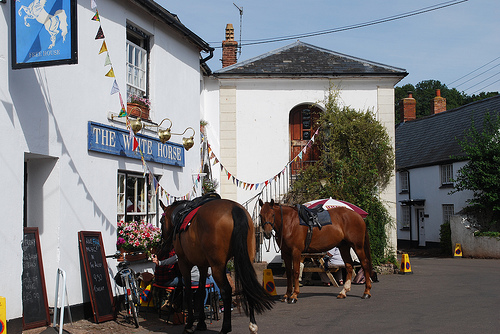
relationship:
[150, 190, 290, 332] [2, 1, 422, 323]
horse near building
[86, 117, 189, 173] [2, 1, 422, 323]
plaque on building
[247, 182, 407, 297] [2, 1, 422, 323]
horse face building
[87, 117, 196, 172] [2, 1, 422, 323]
blue sign on building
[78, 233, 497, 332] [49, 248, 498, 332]
asphalt on ground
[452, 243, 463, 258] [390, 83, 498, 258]
cone next building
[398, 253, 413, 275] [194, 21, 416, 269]
cone next building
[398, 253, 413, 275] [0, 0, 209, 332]
cone next building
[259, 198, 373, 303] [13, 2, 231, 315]
horse next building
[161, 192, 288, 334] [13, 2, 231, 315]
horse next building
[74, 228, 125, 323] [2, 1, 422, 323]
chalk board against building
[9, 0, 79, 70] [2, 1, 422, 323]
sign on building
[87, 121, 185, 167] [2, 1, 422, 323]
blue sign on building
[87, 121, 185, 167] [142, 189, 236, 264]
blue sign above horse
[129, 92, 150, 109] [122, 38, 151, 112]
flowers in window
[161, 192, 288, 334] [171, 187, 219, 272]
horse has coat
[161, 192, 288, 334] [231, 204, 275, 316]
horse has black tail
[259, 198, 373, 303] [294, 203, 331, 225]
horse has saddle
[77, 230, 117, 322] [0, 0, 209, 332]
chalk board leaning on building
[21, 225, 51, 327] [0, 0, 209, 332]
chalkboard leaning on building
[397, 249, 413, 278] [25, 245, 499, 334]
cone on ground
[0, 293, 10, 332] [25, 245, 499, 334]
cone on ground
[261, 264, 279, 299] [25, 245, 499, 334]
cone on ground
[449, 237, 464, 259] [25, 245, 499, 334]
cone on ground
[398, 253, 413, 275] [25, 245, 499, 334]
cone on ground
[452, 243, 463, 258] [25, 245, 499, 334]
cone on ground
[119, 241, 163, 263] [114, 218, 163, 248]
box with flowers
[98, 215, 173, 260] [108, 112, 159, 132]
flowers on ledge